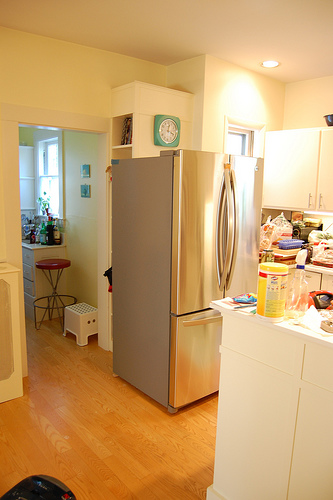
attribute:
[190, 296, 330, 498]
counter — white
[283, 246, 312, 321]
bottle — spray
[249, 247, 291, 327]
container — yellow, plastic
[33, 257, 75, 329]
bar stool — small, red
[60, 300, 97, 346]
step stool — small, white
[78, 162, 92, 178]
painting — small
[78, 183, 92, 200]
painting — small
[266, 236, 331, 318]
bottle — clear, empty, spray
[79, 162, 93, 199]
images — blue, tile-sized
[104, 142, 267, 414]
refrigerator — stainless steel, silver, large, standing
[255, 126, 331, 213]
cabinets — white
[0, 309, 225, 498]
flooring — brown, wooden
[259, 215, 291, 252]
bag — plastic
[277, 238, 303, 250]
plastic container — blue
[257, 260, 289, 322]
wipes — clorox 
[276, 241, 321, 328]
bottle — empty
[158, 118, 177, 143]
clock — green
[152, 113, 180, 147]
clock — green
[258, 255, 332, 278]
counter — congested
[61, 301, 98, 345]
footstool — short, white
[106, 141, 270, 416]
fridge — stainless steel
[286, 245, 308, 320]
bottle — pray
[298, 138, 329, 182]
cabinet — large, white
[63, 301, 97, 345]
step — white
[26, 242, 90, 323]
stool — red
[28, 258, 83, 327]
stool — red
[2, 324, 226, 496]
floors — hardwood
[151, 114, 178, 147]
border — green